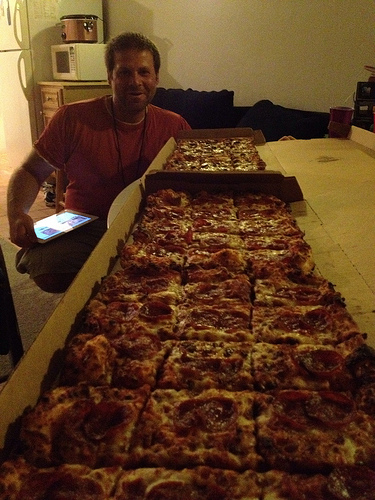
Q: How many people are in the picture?
A: 1.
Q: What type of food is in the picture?
A: Pizza.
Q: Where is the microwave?
A: On table.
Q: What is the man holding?
A: Ipad.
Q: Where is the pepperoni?
A: On pizza.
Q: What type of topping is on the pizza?
A: Pepperoni.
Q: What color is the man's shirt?
A: Orange.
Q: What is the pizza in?
A: Box.